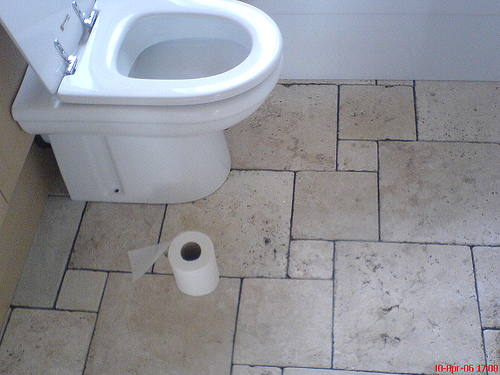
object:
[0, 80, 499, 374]
floor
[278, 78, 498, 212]
ground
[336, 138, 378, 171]
part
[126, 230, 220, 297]
roll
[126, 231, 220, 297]
tissue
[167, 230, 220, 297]
part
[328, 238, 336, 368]
line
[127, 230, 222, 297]
hat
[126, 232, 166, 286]
part